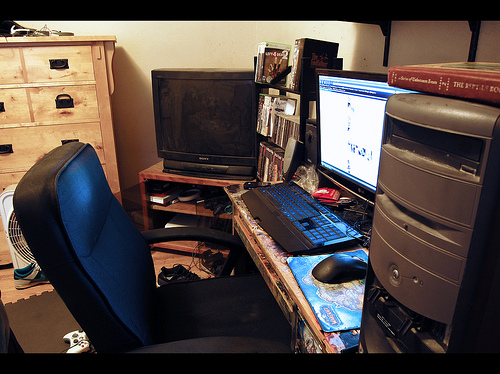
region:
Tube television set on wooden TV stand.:
[150, 67, 258, 178]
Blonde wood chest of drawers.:
[1, 34, 120, 269]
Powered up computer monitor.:
[311, 68, 416, 207]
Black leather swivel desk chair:
[12, 140, 293, 352]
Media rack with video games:
[254, 38, 339, 183]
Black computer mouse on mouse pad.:
[311, 251, 368, 285]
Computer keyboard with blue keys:
[239, 180, 363, 252]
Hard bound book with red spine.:
[386, 59, 498, 103]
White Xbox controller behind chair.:
[61, 328, 88, 353]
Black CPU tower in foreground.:
[358, 89, 494, 357]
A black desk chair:
[15, 140, 292, 352]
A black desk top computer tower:
[356, 90, 497, 354]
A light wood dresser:
[0, 35, 122, 265]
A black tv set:
[149, 67, 270, 179]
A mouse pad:
[286, 249, 371, 334]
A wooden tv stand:
[136, 158, 256, 259]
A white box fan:
[1, 185, 43, 270]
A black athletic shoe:
[158, 263, 200, 284]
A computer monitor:
[312, 68, 422, 222]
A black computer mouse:
[311, 250, 370, 284]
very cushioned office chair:
[15, 140, 285, 355]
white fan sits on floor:
[2, 181, 42, 277]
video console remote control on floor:
[54, 329, 91, 356]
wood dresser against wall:
[2, 22, 133, 243]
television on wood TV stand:
[139, 55, 256, 264]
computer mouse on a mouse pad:
[285, 241, 366, 336]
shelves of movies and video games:
[247, 37, 324, 180]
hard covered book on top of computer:
[388, 47, 495, 107]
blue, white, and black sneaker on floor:
[12, 262, 49, 289]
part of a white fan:
[1, 186, 39, 270]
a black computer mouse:
[312, 253, 369, 285]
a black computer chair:
[12, 143, 281, 370]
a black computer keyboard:
[243, 177, 363, 257]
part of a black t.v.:
[145, 67, 262, 179]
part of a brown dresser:
[0, 34, 131, 204]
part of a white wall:
[131, 23, 246, 62]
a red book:
[377, 61, 499, 95]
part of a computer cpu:
[357, 100, 497, 353]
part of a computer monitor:
[318, 71, 414, 213]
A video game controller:
[62, 327, 89, 352]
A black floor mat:
[2, 288, 97, 354]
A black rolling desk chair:
[10, 138, 294, 359]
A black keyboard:
[242, 178, 363, 254]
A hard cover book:
[388, 58, 498, 102]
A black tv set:
[149, 67, 259, 181]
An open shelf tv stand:
[138, 156, 254, 258]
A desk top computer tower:
[356, 91, 498, 355]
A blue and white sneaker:
[15, 263, 50, 290]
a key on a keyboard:
[277, 187, 281, 190]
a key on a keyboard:
[268, 189, 275, 194]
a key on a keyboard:
[276, 195, 281, 202]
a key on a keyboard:
[287, 209, 289, 213]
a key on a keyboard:
[292, 214, 294, 219]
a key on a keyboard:
[303, 228, 307, 233]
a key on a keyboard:
[303, 227, 310, 234]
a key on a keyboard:
[306, 232, 312, 234]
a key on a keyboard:
[308, 235, 315, 240]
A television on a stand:
[139, 65, 266, 183]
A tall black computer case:
[352, 90, 498, 362]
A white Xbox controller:
[58, 329, 88, 355]